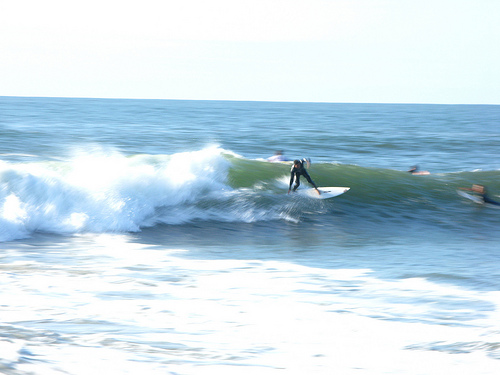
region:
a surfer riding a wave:
[228, 140, 391, 269]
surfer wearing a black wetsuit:
[251, 125, 366, 219]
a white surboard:
[273, 174, 368, 219]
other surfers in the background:
[363, 144, 498, 249]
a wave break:
[1, 122, 498, 267]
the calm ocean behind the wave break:
[5, 100, 498, 185]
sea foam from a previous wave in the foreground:
[4, 226, 439, 373]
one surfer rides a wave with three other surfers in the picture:
[1, 105, 498, 362]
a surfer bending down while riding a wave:
[264, 145, 353, 237]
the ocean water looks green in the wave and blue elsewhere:
[151, 120, 498, 313]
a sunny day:
[22, 111, 499, 368]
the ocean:
[16, 110, 476, 369]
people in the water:
[246, 142, 499, 252]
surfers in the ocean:
[247, 134, 494, 238]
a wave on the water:
[24, 142, 499, 222]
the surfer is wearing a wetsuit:
[277, 149, 359, 214]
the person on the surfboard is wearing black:
[275, 151, 366, 231]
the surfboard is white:
[268, 158, 355, 208]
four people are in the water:
[245, 146, 499, 233]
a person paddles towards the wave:
[457, 183, 499, 221]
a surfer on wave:
[287, 157, 320, 194]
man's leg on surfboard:
[302, 182, 349, 199]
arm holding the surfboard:
[291, 171, 293, 188]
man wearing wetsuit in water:
[288, 154, 328, 191]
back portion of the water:
[75, 115, 260, 137]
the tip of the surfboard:
[337, 184, 350, 194]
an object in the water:
[462, 175, 496, 218]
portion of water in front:
[19, 336, 134, 373]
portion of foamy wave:
[5, 161, 157, 208]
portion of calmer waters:
[412, 107, 492, 143]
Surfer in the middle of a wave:
[277, 160, 326, 225]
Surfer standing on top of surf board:
[284, 154, 341, 222]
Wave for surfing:
[9, 140, 499, 223]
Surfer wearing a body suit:
[258, 158, 365, 226]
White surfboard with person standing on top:
[269, 180, 359, 220]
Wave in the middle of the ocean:
[4, 103, 497, 247]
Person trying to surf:
[377, 157, 452, 197]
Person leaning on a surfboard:
[272, 154, 351, 231]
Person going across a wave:
[10, 151, 488, 226]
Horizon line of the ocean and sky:
[5, 83, 490, 125]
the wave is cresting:
[0, 141, 330, 233]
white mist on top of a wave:
[0, 134, 328, 236]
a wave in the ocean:
[0, 137, 495, 241]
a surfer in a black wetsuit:
[281, 156, 329, 201]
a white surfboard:
[273, 178, 356, 203]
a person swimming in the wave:
[445, 178, 498, 219]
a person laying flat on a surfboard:
[449, 179, 496, 218]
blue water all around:
[0, 98, 492, 275]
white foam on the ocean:
[0, 229, 475, 372]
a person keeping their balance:
[280, 151, 324, 206]